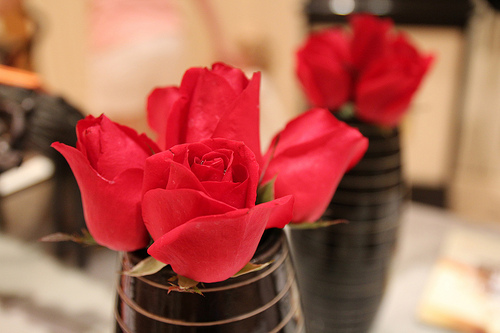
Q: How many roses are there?
A: 4.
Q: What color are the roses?
A: Red.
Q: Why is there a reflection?
A: A mirror.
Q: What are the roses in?
A: Vase.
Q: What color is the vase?
A: Brown.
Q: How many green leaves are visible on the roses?
A: 6.